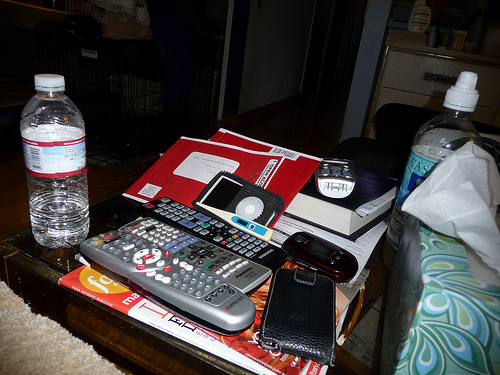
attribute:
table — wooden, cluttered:
[1, 183, 268, 375]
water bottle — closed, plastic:
[22, 65, 92, 249]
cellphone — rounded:
[280, 230, 358, 283]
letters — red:
[115, 123, 324, 230]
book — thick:
[285, 156, 401, 244]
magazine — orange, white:
[57, 254, 362, 374]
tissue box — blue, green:
[379, 140, 499, 374]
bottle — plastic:
[375, 69, 480, 267]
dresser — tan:
[359, 27, 498, 141]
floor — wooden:
[1, 83, 343, 256]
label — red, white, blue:
[15, 132, 92, 177]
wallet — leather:
[255, 264, 340, 369]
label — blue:
[392, 146, 439, 211]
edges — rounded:
[315, 181, 359, 198]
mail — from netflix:
[207, 127, 313, 228]